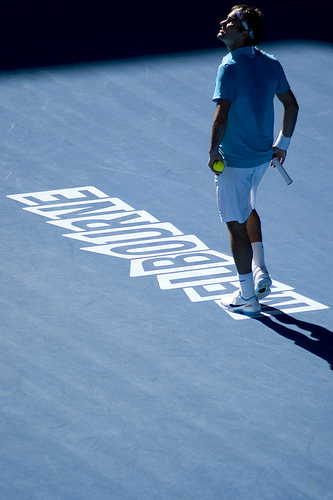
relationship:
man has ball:
[184, 10, 318, 362] [210, 156, 225, 173]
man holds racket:
[184, 10, 318, 362] [272, 156, 293, 186]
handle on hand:
[272, 157, 293, 186] [270, 144, 289, 165]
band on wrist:
[275, 129, 292, 150] [207, 140, 227, 166]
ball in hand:
[214, 158, 226, 173] [204, 150, 227, 176]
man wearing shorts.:
[207, 4, 299, 318] [214, 163, 275, 227]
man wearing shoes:
[207, 4, 299, 318] [200, 246, 292, 325]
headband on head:
[233, 8, 254, 39] [217, 4, 263, 47]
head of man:
[217, 4, 263, 47] [205, 1, 299, 316]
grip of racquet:
[273, 158, 294, 186] [271, 155, 292, 184]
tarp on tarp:
[0, 37, 332, 496] [0, 37, 332, 496]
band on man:
[275, 129, 292, 150] [194, 8, 300, 295]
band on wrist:
[275, 129, 292, 150] [274, 133, 289, 149]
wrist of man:
[274, 133, 289, 149] [194, 8, 300, 295]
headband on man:
[233, 8, 254, 39] [205, 1, 299, 316]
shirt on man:
[215, 3, 298, 165] [205, 1, 299, 316]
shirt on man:
[212, 44, 292, 170] [207, 4, 299, 318]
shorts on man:
[216, 159, 269, 224] [207, 4, 299, 318]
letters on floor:
[5, 186, 330, 321] [0, 296, 332, 497]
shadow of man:
[253, 298, 331, 367] [210, 4, 291, 316]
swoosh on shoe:
[228, 302, 245, 308] [216, 285, 260, 316]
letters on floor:
[1, 176, 332, 346] [2, 132, 332, 385]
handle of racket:
[264, 145, 299, 188] [264, 145, 303, 199]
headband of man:
[224, 0, 299, 60] [207, 4, 299, 318]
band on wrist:
[275, 129, 292, 150] [269, 124, 298, 157]